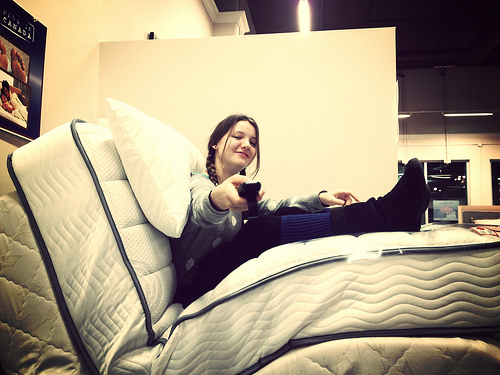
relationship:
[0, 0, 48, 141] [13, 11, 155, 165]
picture on wall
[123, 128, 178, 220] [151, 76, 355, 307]
pillow behind girl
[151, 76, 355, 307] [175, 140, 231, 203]
girl with pigtails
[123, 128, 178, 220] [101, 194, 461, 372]
pillow on bed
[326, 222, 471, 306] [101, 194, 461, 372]
mattress of bed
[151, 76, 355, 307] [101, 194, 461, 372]
girl of bed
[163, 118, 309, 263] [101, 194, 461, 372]
woman on bed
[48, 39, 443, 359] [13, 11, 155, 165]
picture on wall